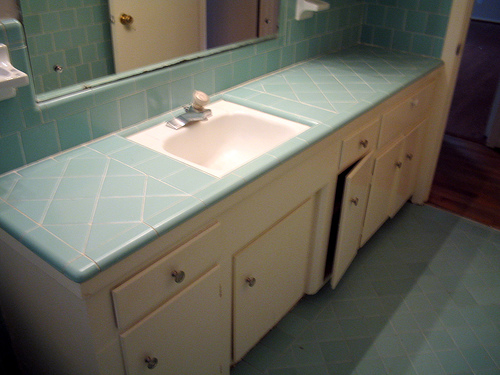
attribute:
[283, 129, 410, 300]
cabinet door — open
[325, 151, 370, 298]
door — open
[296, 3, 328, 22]
holder — for soap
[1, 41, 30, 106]
holder — for toothbrush, white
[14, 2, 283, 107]
mirror — attached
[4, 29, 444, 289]
counter top — blue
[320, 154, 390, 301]
cabinet door — open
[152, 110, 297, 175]
bathroom sink — white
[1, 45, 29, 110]
soap holder — attached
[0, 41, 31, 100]
toothbrush holder — white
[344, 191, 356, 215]
knob — for door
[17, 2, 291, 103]
bathroom mirror — mounted